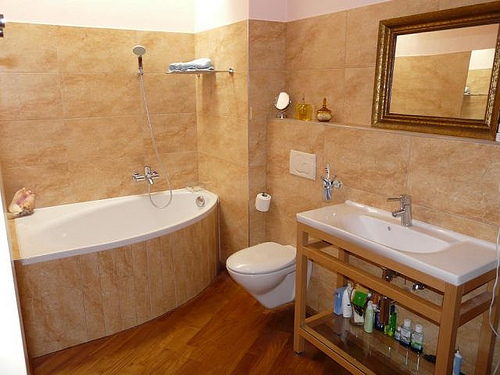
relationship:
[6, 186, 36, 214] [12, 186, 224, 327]
shell on bathtub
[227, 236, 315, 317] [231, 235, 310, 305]
european style toilet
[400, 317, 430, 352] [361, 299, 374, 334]
soaps and shampoos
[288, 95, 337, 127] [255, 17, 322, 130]
oil in corner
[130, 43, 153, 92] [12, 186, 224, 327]
shower over bathtub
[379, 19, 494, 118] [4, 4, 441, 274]
mirror of bathroom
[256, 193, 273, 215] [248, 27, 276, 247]
paper on wall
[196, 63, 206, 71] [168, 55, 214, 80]
blue floded towel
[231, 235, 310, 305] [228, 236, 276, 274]
toilet to sit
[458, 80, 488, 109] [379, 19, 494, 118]
reflections in mirror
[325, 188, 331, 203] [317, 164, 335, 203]
soap dish holder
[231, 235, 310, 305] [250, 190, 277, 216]
toilet tissue roll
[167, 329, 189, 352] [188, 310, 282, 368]
shine wood flooring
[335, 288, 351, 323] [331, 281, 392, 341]
personal hygeine products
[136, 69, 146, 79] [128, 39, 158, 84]
removeable shower head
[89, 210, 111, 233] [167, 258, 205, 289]
white with tile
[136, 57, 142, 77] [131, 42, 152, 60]
handheld shower sprayer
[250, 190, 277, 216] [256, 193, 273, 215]
roll of paper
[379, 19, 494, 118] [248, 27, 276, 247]
mirror on wall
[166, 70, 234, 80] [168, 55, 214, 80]
shelf with towel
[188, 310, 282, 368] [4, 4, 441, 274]
flooring in bathroom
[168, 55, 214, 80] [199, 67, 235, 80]
towel on rack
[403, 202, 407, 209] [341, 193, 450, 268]
silver on sink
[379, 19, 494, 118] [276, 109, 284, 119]
mirror on stand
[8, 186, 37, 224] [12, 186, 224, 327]
shell on bathtub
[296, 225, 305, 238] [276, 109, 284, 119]
wooden sink stand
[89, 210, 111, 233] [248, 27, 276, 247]
white on wall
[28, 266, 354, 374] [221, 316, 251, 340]
flooring of hardwood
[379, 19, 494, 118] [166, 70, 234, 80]
mirror on shelf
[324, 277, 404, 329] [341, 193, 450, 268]
items below sink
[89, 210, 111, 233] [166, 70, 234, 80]
white on shelf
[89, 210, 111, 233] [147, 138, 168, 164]
white power chord